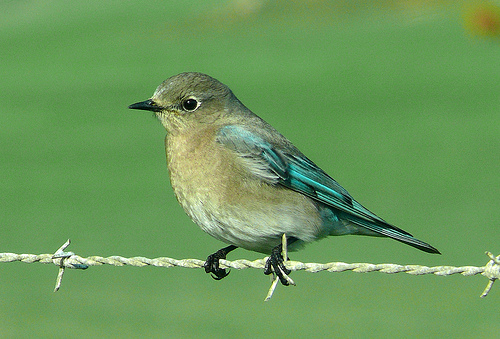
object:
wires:
[0, 252, 500, 276]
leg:
[263, 237, 299, 287]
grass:
[4, 2, 496, 338]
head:
[127, 72, 234, 121]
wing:
[218, 126, 414, 237]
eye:
[181, 97, 201, 113]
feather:
[245, 136, 414, 237]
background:
[1, 1, 498, 336]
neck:
[158, 101, 250, 139]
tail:
[334, 212, 443, 255]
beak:
[127, 98, 164, 111]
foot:
[263, 255, 292, 287]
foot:
[203, 252, 231, 281]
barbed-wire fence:
[0, 234, 500, 303]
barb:
[263, 260, 291, 286]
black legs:
[203, 244, 235, 281]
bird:
[127, 71, 441, 287]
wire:
[80, 251, 400, 273]